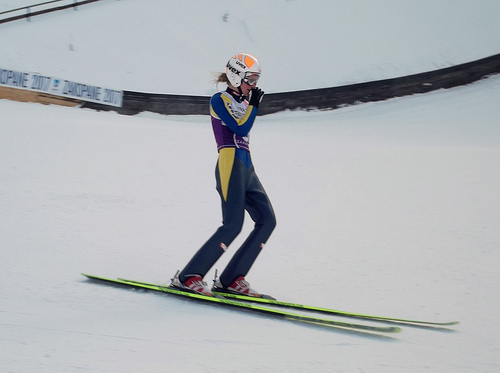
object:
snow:
[1, 0, 500, 372]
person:
[168, 53, 277, 300]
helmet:
[222, 52, 262, 95]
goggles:
[243, 73, 260, 88]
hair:
[210, 72, 229, 91]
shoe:
[167, 269, 225, 299]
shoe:
[210, 269, 278, 301]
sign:
[0, 68, 125, 108]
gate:
[0, 0, 499, 116]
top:
[209, 87, 264, 154]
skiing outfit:
[80, 52, 459, 332]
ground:
[1, 0, 500, 372]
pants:
[178, 147, 276, 292]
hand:
[246, 87, 266, 105]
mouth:
[244, 87, 252, 93]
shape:
[243, 55, 255, 70]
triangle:
[217, 146, 236, 201]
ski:
[117, 277, 461, 326]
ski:
[80, 272, 400, 332]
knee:
[251, 211, 278, 236]